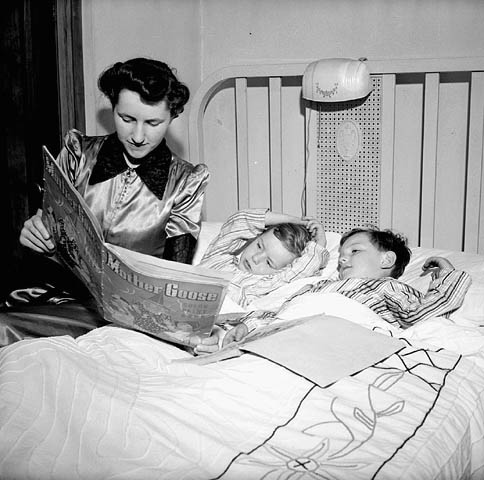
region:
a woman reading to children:
[38, 54, 434, 369]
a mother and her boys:
[39, 71, 431, 374]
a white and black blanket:
[19, 298, 458, 478]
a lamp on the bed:
[270, 57, 384, 117]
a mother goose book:
[38, 153, 235, 365]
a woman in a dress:
[12, 65, 224, 385]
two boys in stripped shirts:
[201, 199, 459, 351]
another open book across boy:
[156, 295, 397, 415]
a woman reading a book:
[22, 41, 259, 386]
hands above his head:
[220, 190, 375, 291]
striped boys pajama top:
[261, 272, 472, 326]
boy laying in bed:
[290, 226, 469, 360]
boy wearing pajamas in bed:
[199, 209, 330, 314]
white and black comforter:
[10, 312, 483, 477]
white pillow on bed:
[404, 248, 482, 339]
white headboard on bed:
[192, 63, 482, 252]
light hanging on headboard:
[303, 58, 374, 104]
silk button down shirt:
[44, 130, 207, 261]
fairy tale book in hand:
[40, 147, 227, 348]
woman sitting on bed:
[6, 56, 204, 340]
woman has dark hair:
[106, 30, 220, 140]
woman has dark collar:
[102, 131, 175, 212]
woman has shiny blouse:
[67, 138, 217, 261]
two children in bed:
[193, 233, 411, 354]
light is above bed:
[298, 55, 386, 125]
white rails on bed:
[192, 62, 471, 218]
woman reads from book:
[16, 146, 275, 327]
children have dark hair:
[264, 185, 428, 287]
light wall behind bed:
[167, 20, 480, 61]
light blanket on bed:
[27, 368, 275, 474]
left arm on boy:
[421, 242, 477, 311]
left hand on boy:
[408, 253, 456, 280]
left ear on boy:
[368, 239, 407, 279]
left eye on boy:
[346, 229, 368, 263]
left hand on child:
[307, 220, 333, 251]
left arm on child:
[285, 231, 331, 282]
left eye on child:
[258, 248, 289, 280]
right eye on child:
[251, 235, 282, 255]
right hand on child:
[243, 197, 330, 253]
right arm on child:
[224, 213, 311, 235]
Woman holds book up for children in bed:
[13, 54, 472, 368]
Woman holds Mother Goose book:
[20, 53, 232, 352]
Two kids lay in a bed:
[188, 204, 471, 327]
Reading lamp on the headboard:
[298, 58, 376, 106]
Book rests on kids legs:
[167, 310, 409, 389]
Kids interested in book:
[191, 207, 471, 333]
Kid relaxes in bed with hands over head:
[187, 204, 330, 305]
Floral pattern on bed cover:
[208, 321, 464, 479]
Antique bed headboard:
[182, 53, 482, 258]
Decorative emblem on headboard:
[331, 116, 362, 161]